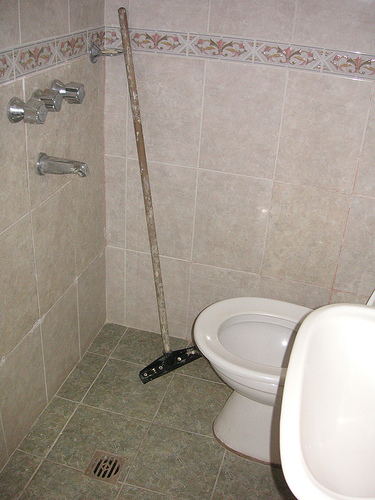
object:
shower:
[5, 79, 69, 131]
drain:
[85, 449, 124, 484]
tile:
[72, 359, 124, 422]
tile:
[128, 422, 225, 495]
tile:
[18, 398, 77, 459]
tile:
[88, 322, 128, 358]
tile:
[20, 460, 123, 499]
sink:
[280, 300, 373, 499]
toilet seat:
[192, 296, 312, 381]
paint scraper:
[118, 8, 201, 384]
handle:
[118, 4, 177, 351]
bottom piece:
[138, 347, 203, 383]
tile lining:
[1, 27, 374, 85]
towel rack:
[88, 44, 121, 63]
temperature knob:
[8, 98, 48, 123]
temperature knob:
[54, 80, 86, 103]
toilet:
[193, 272, 374, 468]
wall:
[1, 0, 104, 469]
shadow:
[271, 303, 326, 500]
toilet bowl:
[192, 290, 315, 467]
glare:
[281, 338, 287, 346]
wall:
[102, 3, 372, 343]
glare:
[258, 208, 268, 214]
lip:
[277, 301, 372, 499]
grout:
[45, 457, 122, 485]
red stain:
[48, 460, 81, 472]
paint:
[119, 10, 169, 355]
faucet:
[38, 151, 89, 178]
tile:
[197, 60, 287, 174]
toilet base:
[209, 388, 285, 464]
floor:
[0, 321, 295, 500]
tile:
[276, 67, 370, 197]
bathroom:
[1, 0, 373, 498]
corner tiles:
[70, 0, 126, 358]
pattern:
[173, 32, 233, 60]